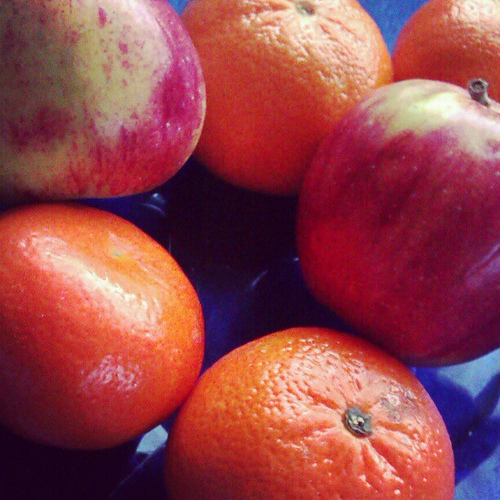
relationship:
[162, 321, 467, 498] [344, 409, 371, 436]
orange has dimple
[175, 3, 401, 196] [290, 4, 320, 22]
orange has dimple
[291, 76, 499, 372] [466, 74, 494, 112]
apple has stem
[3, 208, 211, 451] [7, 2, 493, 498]
orange on blue cloth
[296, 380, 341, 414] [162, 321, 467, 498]
mark on orange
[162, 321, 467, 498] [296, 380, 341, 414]
orange has mark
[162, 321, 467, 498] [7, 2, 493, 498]
orange on blue cloth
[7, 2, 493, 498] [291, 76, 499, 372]
blue cloth under apple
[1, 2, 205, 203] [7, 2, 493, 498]
apple on blue cloth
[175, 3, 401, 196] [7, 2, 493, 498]
orange on blue cloth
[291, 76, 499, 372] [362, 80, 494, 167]
apple has patch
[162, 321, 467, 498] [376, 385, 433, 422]
orange has bruise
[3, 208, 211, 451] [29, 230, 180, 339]
orange reflects light